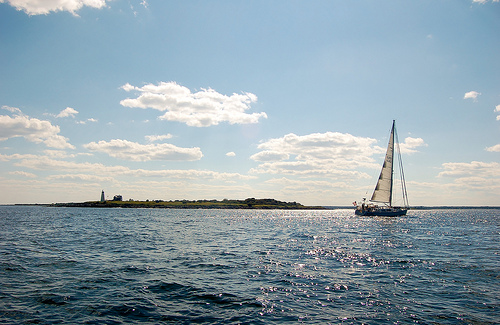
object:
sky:
[2, 0, 498, 208]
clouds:
[463, 90, 480, 103]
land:
[33, 198, 303, 209]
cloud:
[120, 78, 266, 128]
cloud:
[49, 107, 80, 119]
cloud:
[250, 132, 428, 174]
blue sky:
[112, 23, 293, 133]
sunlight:
[318, 244, 342, 256]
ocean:
[0, 203, 498, 318]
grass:
[168, 202, 218, 205]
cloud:
[83, 132, 207, 163]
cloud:
[0, 104, 76, 151]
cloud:
[1, 0, 116, 22]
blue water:
[38, 221, 370, 318]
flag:
[352, 201, 358, 207]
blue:
[355, 211, 407, 216]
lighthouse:
[100, 189, 104, 202]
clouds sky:
[45, 38, 265, 130]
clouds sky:
[241, 130, 351, 185]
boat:
[351, 119, 411, 216]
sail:
[369, 120, 394, 204]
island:
[18, 190, 346, 210]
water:
[0, 207, 496, 325]